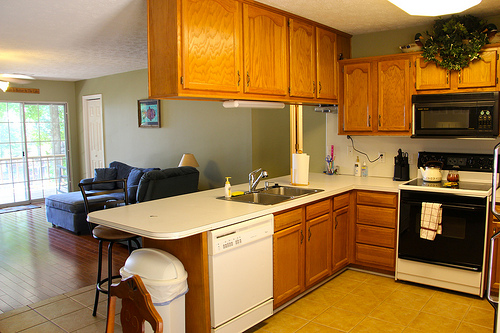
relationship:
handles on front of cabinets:
[236, 68, 251, 87] [146, 1, 499, 138]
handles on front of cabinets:
[308, 77, 324, 94] [146, 1, 499, 138]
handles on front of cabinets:
[363, 112, 383, 131] [146, 1, 499, 138]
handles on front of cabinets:
[297, 225, 313, 244] [146, 1, 499, 138]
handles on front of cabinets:
[443, 66, 462, 86] [146, 1, 499, 138]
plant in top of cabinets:
[417, 13, 490, 71] [146, 1, 499, 138]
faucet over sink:
[248, 163, 268, 192] [217, 182, 323, 205]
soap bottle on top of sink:
[221, 174, 232, 198] [217, 182, 323, 205]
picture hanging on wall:
[134, 96, 164, 129] [74, 69, 253, 191]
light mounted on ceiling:
[386, 1, 482, 18] [259, 0, 499, 35]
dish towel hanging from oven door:
[418, 197, 444, 242] [397, 186, 487, 273]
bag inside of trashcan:
[119, 265, 188, 309] [118, 247, 190, 332]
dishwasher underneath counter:
[207, 213, 275, 332] [86, 170, 410, 240]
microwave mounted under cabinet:
[410, 91, 498, 139] [411, 47, 498, 92]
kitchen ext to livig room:
[88, 1, 499, 333] [0, 1, 252, 315]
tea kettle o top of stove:
[419, 157, 442, 183] [401, 176, 491, 193]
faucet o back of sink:
[248, 163, 268, 192] [217, 182, 323, 205]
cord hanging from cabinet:
[343, 133, 382, 162] [336, 57, 411, 136]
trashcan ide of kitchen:
[118, 247, 190, 332] [88, 1, 499, 333]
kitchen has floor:
[88, 1, 499, 333] [240, 269, 494, 331]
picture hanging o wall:
[134, 96, 164, 129] [74, 69, 253, 191]